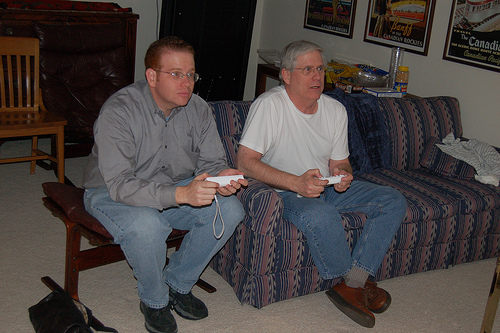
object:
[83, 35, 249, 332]
man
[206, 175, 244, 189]
controller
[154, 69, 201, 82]
glasses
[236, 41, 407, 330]
man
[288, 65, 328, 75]
glasses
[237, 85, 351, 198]
shirt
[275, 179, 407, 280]
blue jeans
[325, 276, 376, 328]
shoe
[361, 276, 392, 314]
shoe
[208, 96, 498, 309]
sofa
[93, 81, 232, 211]
shirt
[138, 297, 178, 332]
shoe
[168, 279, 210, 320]
shoe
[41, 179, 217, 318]
seat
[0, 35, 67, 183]
chair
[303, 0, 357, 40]
framed poster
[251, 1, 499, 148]
wall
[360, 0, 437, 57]
framed poster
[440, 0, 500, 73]
framed poster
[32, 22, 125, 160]
recliner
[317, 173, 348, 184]
controller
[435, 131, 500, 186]
shirt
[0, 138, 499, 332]
carpet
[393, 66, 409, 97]
container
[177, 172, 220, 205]
hand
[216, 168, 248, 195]
hand